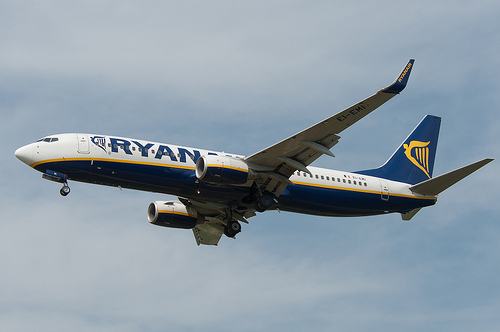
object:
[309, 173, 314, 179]
window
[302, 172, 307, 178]
window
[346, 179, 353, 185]
glass window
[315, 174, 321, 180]
small window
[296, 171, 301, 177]
window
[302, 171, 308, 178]
glass window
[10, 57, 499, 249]
airplane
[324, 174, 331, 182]
small window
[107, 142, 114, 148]
window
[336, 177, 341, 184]
window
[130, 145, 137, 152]
window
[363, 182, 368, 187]
window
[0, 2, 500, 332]
sky